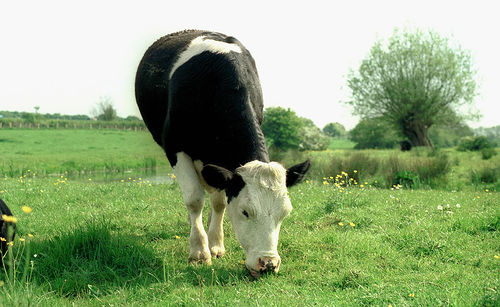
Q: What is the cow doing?
A: Grazing.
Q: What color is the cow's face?
A: White.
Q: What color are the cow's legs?
A: White.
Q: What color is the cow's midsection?
A: Mostly black with white patches.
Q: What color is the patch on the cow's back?
A: White.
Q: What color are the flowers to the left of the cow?
A: Yellow.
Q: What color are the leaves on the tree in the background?
A: Green.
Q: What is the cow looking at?
A: Grass.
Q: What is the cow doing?
A: Eating.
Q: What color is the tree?
A: Green.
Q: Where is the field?
A: Behind the cow.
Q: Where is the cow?
A: Pasture.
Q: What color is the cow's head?
A: White.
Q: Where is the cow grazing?
A: Pasture.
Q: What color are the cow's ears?
A: Black.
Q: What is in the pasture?
A: Green grass.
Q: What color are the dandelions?
A: Yellow.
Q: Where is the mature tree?
A: In the right side background.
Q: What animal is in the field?
A: A cow.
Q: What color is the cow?
A: Black and white.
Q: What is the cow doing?
A: Eating grass.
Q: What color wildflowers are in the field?
A: Yellow and white.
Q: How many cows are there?
A: One.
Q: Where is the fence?
A: Along the back of the field.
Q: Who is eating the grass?
A: The cow.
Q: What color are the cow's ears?
A: Black.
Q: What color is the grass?
A: Green.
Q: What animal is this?
A: A cow.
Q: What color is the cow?
A: It is white and black.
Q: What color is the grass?
A: It is green.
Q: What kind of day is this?
A: Sunny and clear.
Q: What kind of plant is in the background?
A: A tree.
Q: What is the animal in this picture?
A: Cow.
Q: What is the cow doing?
A: Eating grass.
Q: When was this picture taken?
A: Day time.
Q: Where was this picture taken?
A: A pasture.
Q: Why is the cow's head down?
A: It is eating.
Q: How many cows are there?
A: 1.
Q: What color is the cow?
A: Black and white.